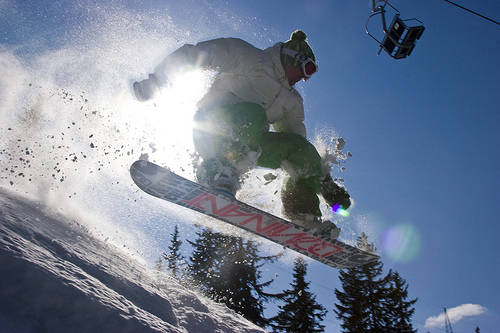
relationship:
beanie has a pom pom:
[280, 29, 317, 66] [289, 28, 308, 41]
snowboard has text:
[129, 157, 380, 270] [181, 191, 345, 260]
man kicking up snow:
[132, 30, 352, 239] [2, 2, 348, 256]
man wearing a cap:
[132, 30, 352, 239] [279, 27, 316, 67]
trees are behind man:
[170, 221, 419, 333] [132, 30, 352, 239]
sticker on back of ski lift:
[393, 20, 400, 32] [365, 2, 427, 63]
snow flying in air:
[2, 2, 348, 256] [2, 4, 499, 332]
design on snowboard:
[135, 163, 363, 268] [129, 157, 380, 270]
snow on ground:
[2, 187, 269, 333] [1, 186, 299, 332]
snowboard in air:
[129, 157, 380, 270] [2, 4, 499, 332]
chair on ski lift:
[381, 17, 426, 60] [365, 2, 427, 63]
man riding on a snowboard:
[129, 27, 354, 242] [129, 157, 380, 270]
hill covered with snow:
[0, 183, 269, 333] [2, 187, 269, 333]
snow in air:
[2, 2, 348, 256] [2, 4, 499, 332]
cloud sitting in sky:
[420, 302, 491, 332] [2, 2, 499, 333]